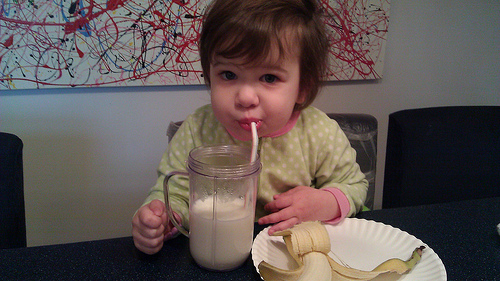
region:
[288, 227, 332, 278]
a banana on the paper plate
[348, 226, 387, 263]
a white plate on the table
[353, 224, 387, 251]
a white paper plate on the table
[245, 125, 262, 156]
a straw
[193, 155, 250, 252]
a glass with milk inside of it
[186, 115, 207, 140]
girl is wearing a green shirt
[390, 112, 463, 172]
dark blue chair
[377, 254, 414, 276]
a banana peal on the plate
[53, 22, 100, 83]
some kind of art picture on the wall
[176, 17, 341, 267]
girl is sipping milk while eating a banana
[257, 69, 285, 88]
A baby's left eye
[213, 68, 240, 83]
A baby's right eye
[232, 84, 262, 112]
A baby's nose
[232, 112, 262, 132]
A baby's mouth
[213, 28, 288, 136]
A baby's face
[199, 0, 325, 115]
A baby's black short hair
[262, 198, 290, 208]
A baby's finger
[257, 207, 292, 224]
A baby's finger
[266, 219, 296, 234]
A baby's finger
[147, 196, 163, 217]
A baby's finger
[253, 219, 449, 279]
a white plate sitting on the table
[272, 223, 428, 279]
a banana on the plate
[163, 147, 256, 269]
a plastic cup full of milk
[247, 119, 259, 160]
the straw sticking out of the cup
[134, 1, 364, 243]
the kid sitting at the table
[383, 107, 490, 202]
the black chair sitting at the table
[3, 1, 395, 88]
the painting on the wall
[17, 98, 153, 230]
the wall underneath the painting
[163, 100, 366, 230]
the pajamas the kid is wearing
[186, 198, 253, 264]
the milk in the cup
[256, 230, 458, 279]
A peeled banana on a plate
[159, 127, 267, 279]
A cup full of milk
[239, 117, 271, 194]
A straw to drink from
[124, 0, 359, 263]
A baby drinking milk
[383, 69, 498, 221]
A blue seat cushion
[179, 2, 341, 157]
A baby face with short light brown hair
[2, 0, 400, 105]
A painting of splattered paint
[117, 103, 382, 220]
A green shirt with white polka dots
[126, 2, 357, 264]
A toddler gazing at the camera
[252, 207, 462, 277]
A paper plate with a peeled banana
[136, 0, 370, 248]
a toddler drinking milk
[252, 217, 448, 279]
banana peel on a paper plate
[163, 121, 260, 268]
a plastic cup with a handle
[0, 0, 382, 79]
a large abstract painting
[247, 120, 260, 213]
a striped bendy straw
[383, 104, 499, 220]
a black chair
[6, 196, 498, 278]
a black table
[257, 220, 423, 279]
a banana with the peel half on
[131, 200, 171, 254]
a closed hand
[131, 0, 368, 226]
a toddler wearing a green polka dot shirt